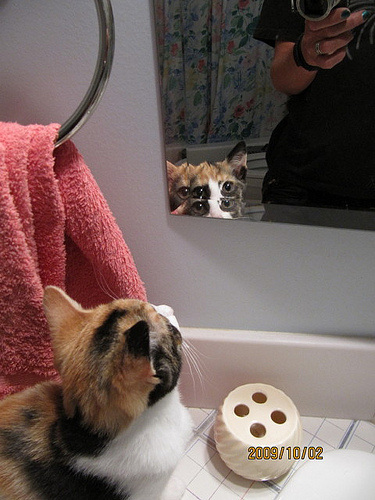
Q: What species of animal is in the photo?
A: A cat.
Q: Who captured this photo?
A: A photographer.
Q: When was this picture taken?
A: During waking hours.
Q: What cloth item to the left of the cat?
A: A towel.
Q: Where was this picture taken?
A: Bathroom.